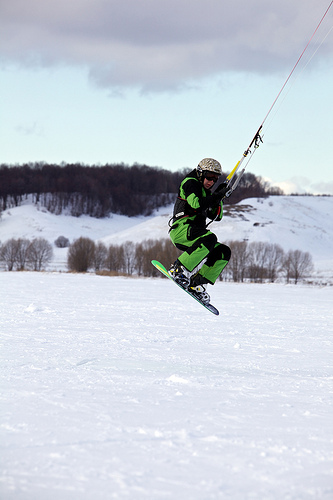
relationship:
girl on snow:
[183, 146, 235, 284] [81, 311, 167, 374]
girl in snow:
[183, 146, 235, 284] [81, 311, 167, 374]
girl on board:
[183, 146, 235, 284] [149, 264, 215, 324]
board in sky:
[149, 264, 215, 324] [95, 58, 155, 104]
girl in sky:
[183, 146, 235, 284] [95, 58, 155, 104]